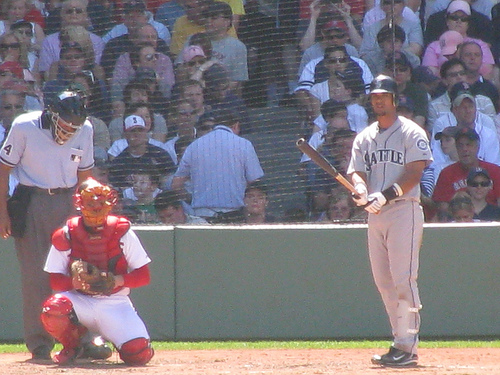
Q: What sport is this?
A: Baseball.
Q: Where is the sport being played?
A: Baseball field.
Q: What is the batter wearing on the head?
A: Helmet.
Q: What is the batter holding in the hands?
A: Bat.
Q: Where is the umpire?
A: Behind the catcher.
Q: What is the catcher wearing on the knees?
A: Knee pads.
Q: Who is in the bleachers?
A: Sport spectators.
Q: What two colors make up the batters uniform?
A: Grey and blue.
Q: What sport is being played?
A: Baseball.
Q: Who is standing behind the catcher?
A: Umpire.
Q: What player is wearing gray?
A: Batter.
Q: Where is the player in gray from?
A: Seattle.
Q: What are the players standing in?
A: Dirt.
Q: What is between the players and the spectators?
A: Net.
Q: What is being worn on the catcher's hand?
A: Mitt.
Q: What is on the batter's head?
A: Helmet.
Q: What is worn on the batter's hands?
A: Gloves.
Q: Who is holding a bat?
A: A baseball player.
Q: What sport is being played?
A: BAseball.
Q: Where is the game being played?
A: Baseball field.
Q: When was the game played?
A: During daylight hours.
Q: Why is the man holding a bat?
A: Getting ready to hit a ball.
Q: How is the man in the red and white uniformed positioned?
A: On his knees.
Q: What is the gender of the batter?
A: Male.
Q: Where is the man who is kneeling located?
A: Behind the batter.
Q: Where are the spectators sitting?
A: In the stands.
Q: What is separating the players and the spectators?
A: A fence.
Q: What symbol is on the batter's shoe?
A: Nike swoosh.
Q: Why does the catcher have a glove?
A: To catch the ball.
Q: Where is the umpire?
A: Behind the catcher.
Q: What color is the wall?
A: Green.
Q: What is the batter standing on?
A: The ground.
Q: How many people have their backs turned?
A: One.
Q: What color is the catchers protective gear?
A: Red.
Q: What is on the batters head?
A: A helmet.